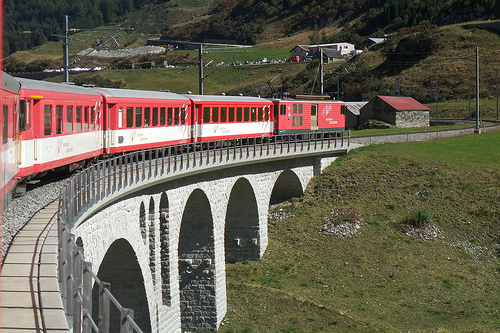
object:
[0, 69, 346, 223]
train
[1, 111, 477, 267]
tracks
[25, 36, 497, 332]
grass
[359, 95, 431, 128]
building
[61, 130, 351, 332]
bridge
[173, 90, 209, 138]
train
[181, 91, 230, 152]
train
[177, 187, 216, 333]
arch way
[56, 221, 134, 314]
fencing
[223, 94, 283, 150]
train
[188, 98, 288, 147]
train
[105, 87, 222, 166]
train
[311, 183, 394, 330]
hillside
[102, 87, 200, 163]
train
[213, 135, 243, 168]
railroad track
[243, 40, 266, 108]
power lines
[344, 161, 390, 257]
hill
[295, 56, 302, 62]
barrel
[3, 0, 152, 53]
trees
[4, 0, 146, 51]
forest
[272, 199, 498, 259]
landscape